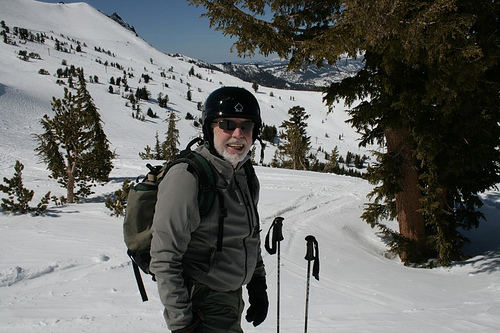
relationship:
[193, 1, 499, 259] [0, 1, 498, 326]
pine tree in snow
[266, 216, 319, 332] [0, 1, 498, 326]
ski poles are in snow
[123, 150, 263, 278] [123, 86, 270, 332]
backpack on man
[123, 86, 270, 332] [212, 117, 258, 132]
man wearing sunglasses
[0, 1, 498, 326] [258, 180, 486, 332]
snow has tracks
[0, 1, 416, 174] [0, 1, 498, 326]
mountain has snow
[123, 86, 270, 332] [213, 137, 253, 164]
man has beard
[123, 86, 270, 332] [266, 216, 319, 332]
man has ski poles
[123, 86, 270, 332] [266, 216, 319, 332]
man posing with ski poles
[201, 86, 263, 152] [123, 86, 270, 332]
helmet on top of man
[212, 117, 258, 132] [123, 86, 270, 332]
sunglasses are on man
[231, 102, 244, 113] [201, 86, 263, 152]
logo on helmet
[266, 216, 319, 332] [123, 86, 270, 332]
ski poles are next to man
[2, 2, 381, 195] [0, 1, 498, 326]
trees are in snow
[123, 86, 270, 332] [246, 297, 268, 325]
man has a glove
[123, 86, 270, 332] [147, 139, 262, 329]
man has a jacket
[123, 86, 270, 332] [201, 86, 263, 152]
man wearing a helmet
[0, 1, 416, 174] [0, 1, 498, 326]
mountain covered with snow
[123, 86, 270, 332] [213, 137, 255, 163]
man has a beard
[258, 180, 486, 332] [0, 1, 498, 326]
tracks are in snow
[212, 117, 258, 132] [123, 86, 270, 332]
sunglasses of man